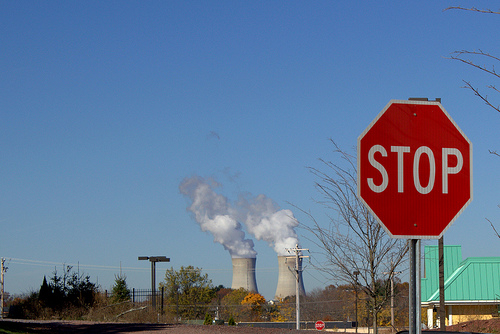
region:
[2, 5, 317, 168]
cloudless clear blue sky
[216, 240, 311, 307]
two cement smoke stacks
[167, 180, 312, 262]
air pollution from two smoke stacks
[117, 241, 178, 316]
dark metal telephone poles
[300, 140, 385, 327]
tree branches without leaves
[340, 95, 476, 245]
red and white stop sign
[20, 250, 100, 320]
copse of pine trees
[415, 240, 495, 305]
light green metal roof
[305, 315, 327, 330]
red and white stop sign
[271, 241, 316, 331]
wooden telephone poles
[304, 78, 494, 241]
the sign says stop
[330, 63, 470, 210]
the sign is red and white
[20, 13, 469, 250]
the sky is blue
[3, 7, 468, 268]
there are no clouds in the sky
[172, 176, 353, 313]
the buildings have steam coming out of them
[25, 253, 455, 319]
trees are surrounding the buildings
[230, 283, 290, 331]
the tree has orange leaves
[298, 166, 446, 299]
the tree has no branches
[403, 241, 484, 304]
the building's roof is green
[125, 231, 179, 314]
the street light is off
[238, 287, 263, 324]
a tree in a distance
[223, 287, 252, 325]
a tree in a distance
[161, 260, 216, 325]
a tree in a distance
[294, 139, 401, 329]
a tree in a distance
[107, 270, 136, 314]
a tree in a distance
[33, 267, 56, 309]
a tree in a distance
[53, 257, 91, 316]
a tree in a distance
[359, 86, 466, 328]
a stop sign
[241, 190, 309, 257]
white smoke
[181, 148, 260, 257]
white smoke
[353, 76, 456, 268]
Red sign on side of road.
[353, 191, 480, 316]
Red sign says STOP.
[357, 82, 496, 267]
STOP is written in white lettering.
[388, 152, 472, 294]
Red sign connected to silver pole.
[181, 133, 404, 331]
Smoke coming out of top of gray buildings.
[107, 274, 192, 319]
Dark fence near trees.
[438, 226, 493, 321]
Roof on building is green.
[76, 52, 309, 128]
Sky is clear and blue.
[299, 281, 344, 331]
Stop sign in distance.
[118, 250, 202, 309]
Light post near trees.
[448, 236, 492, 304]
Building has green roof.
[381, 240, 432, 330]
Stop sign has silver pole.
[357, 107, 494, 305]
Sign is red in color.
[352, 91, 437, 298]
Writing on red sign is white.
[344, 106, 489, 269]
Sign has 8 sides.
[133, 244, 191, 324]
Tall black light post in distance.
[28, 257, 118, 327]
Tall trees in distance.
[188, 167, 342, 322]
Smoke coming out of top of power plant buildings.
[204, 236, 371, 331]
Buildings are gray concrete.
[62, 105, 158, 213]
Sky is clear and blue.